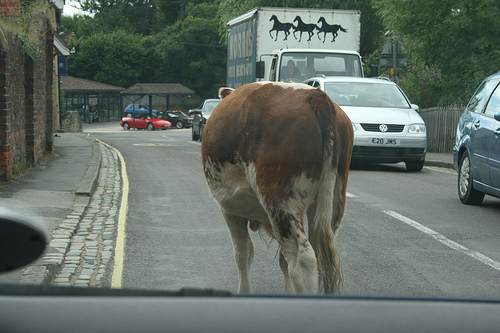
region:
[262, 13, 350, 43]
The horse decal on the big truck.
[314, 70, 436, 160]
The car in front of the big truck.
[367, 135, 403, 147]
The license plate number of the car in front of the big truck.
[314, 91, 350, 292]
The tail of the cow in the street.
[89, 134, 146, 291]
The yellow line on the left side of the street.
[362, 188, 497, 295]
The white line in the middle of the street.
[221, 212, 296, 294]
The front legs of the cow.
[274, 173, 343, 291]
The back legs of the cow.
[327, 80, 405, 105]
The front windshield window of the car in front of the big truck.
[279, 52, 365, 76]
The front windshield window of the big truck.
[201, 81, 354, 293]
a cow in the street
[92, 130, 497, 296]
paved street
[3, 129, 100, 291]
sidewalk along the edge of the street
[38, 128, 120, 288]
bricks on the edge of the sidewalk and the street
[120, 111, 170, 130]
red car in the background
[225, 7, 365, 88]
a truck on the street behind the cow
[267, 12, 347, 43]
three horses painted on the top of the truck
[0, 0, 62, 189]
brick building along the side of the street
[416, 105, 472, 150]
fence along the side of the street at the far side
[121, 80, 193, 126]
an awning with cars parked under it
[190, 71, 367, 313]
animal on a street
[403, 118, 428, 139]
front headlight of a vehicle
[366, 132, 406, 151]
front licence plate on a vehicle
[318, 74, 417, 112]
front windshield on a vehicle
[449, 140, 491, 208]
rear wheel on a vehicle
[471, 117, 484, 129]
door handle on a vehicle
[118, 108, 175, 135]
red car parked in a lot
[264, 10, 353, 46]
black horses painted on a truck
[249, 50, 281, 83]
side rear view mirror on a truck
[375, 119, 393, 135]
logo on the front of a car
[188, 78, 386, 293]
Cow walking down street in front of vehicle.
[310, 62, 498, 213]
Cars moving down street in traffic.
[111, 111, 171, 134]
Red car parked in parking lot.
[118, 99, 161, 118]
Blue car parked in parking lot.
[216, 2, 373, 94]
Truck moving down street in traffic.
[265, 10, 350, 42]
Three black horses painted across top of truck.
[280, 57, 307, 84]
A man driving truck.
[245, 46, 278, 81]
Side view mirror on truck.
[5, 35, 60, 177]
Red brick wall of building next to sidewalk.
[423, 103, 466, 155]
Wood fence next to sidewalk.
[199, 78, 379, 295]
A cow on a road.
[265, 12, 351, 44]
Pictures of horses on a truck.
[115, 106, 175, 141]
A parked red convertible.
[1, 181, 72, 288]
A part of a car side mirror.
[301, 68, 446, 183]
A silver car on the road.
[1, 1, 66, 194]
The side of a building.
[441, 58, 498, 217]
Half of a blue car.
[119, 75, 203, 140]
A car port with cars.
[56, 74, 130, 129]
A large brown building.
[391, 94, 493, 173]
A wooden fence behind a car.